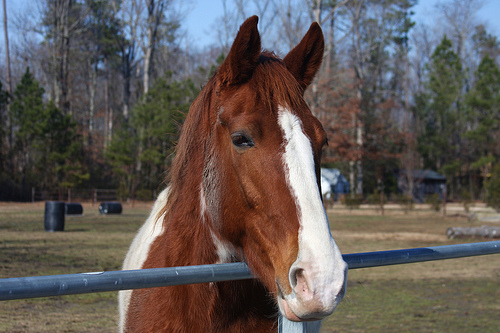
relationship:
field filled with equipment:
[1, 185, 426, 329] [32, 194, 145, 255]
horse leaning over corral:
[162, 5, 380, 330] [0, 239, 500, 333]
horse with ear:
[117, 14, 346, 333] [224, 11, 269, 75]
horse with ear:
[117, 14, 346, 333] [282, 22, 352, 109]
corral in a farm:
[0, 239, 500, 333] [9, 166, 478, 330]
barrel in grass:
[43, 199, 66, 233] [31, 227, 82, 253]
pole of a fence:
[0, 238, 499, 302] [7, 245, 487, 330]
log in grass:
[448, 218, 496, 250] [412, 221, 491, 272]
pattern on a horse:
[260, 92, 330, 248] [167, 9, 360, 311]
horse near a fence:
[117, 14, 346, 333] [140, 232, 273, 330]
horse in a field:
[162, 5, 380, 330] [20, 210, 142, 330]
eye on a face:
[222, 125, 260, 157] [179, 33, 366, 329]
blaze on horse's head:
[257, 90, 333, 264] [173, 13, 382, 330]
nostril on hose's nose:
[285, 269, 305, 294] [279, 259, 339, 313]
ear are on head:
[221, 14, 261, 85] [199, 15, 349, 322]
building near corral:
[116, 22, 349, 331] [4, 184, 496, 327]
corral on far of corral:
[0, 239, 500, 333] [4, 184, 496, 327]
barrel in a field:
[90, 195, 125, 225] [5, 199, 497, 330]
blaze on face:
[256, 105, 333, 245] [206, 49, 349, 321]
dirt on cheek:
[200, 136, 220, 239] [201, 103, 253, 256]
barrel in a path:
[43, 193, 73, 233] [0, 207, 496, 330]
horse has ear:
[117, 14, 346, 333] [212, 10, 265, 86]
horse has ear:
[117, 14, 346, 333] [283, 18, 325, 90]